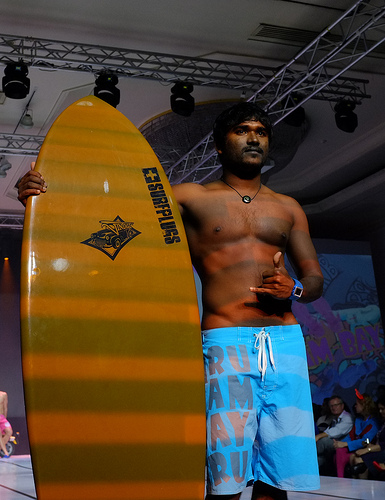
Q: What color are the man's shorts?
A: Blue.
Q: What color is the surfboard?
A: Yellow.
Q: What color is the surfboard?
A: Orange.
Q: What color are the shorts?
A: Blue.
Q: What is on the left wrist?
A: Smart watch.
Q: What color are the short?
A: Blue.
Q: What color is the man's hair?
A: Black.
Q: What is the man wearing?
A: Board shorts.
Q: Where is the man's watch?
A: Left wrist.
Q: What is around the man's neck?
A: Necklace.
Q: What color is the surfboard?
A: Yellow.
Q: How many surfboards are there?
A: One.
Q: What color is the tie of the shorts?
A: White.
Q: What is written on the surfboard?
A: SURFPLUGS.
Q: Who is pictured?
A: A model.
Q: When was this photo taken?
A: During a runway shoot.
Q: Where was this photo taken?
A: On a runway.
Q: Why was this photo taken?
A: To capture the model.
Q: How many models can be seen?
A: Just 1.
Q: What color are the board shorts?
A: They are blue.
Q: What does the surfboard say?
A: Surfplugs.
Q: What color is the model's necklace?
A: It is black and silver.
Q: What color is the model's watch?
A: It is blue.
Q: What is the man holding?
A: A surfboard.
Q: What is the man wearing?
A: Shorts.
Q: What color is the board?
A: Orange.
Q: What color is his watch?
A: Blue.